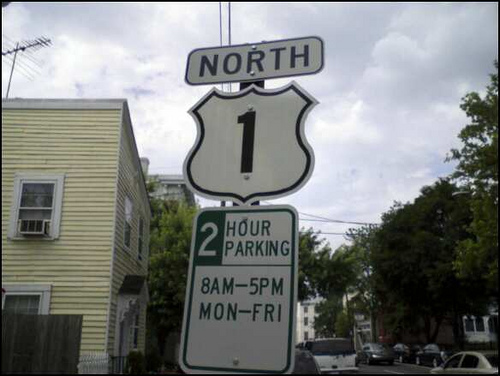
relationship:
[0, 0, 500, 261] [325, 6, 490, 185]
clouds in sky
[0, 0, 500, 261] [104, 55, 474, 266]
clouds in sky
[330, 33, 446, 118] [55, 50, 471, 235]
clouds in sky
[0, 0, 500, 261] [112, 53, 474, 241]
clouds in sky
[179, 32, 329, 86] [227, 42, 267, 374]
sign on post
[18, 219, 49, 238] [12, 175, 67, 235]
ac in window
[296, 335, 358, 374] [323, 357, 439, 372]
suv parked on street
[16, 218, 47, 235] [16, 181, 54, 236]
ac in window